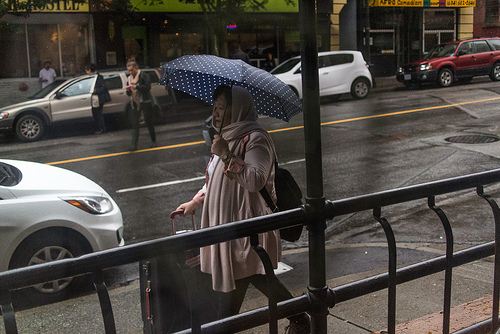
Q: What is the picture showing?
A: It is showing a street.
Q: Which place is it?
A: It is a street.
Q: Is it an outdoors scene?
A: Yes, it is outdoors.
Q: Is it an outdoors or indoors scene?
A: It is outdoors.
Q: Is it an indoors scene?
A: No, it is outdoors.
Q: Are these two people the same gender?
A: Yes, all the people are female.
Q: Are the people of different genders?
A: No, all the people are female.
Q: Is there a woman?
A: Yes, there is a woman.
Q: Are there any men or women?
A: Yes, there is a woman.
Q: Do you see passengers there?
A: No, there are no passengers.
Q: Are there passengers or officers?
A: No, there are no passengers or officers.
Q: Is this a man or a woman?
A: This is a woman.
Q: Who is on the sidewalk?
A: The woman is on the sidewalk.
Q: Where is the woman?
A: The woman is on the sidewalk.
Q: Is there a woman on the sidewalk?
A: Yes, there is a woman on the sidewalk.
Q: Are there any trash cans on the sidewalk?
A: No, there is a woman on the sidewalk.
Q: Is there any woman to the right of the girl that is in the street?
A: Yes, there is a woman to the right of the girl.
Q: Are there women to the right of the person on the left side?
A: Yes, there is a woman to the right of the girl.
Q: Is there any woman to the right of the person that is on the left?
A: Yes, there is a woman to the right of the girl.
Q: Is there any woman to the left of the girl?
A: No, the woman is to the right of the girl.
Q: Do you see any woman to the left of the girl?
A: No, the woman is to the right of the girl.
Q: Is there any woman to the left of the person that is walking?
A: No, the woman is to the right of the girl.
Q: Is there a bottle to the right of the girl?
A: No, there is a woman to the right of the girl.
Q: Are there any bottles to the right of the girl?
A: No, there is a woman to the right of the girl.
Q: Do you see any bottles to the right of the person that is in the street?
A: No, there is a woman to the right of the girl.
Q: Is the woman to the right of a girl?
A: Yes, the woman is to the right of a girl.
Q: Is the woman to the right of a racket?
A: No, the woman is to the right of a girl.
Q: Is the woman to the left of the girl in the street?
A: No, the woman is to the right of the girl.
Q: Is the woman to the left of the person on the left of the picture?
A: No, the woman is to the right of the girl.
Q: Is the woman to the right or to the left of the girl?
A: The woman is to the right of the girl.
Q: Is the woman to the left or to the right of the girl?
A: The woman is to the right of the girl.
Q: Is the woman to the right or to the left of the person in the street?
A: The woman is to the right of the girl.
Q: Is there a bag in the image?
A: Yes, there is a bag.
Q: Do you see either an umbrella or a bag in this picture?
A: Yes, there is a bag.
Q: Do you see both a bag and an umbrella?
A: Yes, there are both a bag and an umbrella.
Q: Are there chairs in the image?
A: No, there are no chairs.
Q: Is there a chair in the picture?
A: No, there are no chairs.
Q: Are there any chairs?
A: No, there are no chairs.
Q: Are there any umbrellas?
A: Yes, there is an umbrella.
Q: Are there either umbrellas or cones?
A: Yes, there is an umbrella.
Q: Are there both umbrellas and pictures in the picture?
A: No, there is an umbrella but no pictures.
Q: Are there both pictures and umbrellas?
A: No, there is an umbrella but no pictures.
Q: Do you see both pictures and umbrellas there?
A: No, there is an umbrella but no pictures.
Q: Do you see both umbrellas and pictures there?
A: No, there is an umbrella but no pictures.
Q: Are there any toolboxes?
A: No, there are no toolboxes.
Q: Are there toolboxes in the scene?
A: No, there are no toolboxes.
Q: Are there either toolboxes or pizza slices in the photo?
A: No, there are no toolboxes or pizza slices.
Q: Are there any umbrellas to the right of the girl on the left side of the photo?
A: Yes, there is an umbrella to the right of the girl.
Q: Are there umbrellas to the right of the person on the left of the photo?
A: Yes, there is an umbrella to the right of the girl.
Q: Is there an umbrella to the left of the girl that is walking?
A: No, the umbrella is to the right of the girl.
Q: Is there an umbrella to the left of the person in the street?
A: No, the umbrella is to the right of the girl.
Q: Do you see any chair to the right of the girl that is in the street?
A: No, there is an umbrella to the right of the girl.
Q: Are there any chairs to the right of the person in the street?
A: No, there is an umbrella to the right of the girl.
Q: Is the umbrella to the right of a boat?
A: No, the umbrella is to the right of the girl.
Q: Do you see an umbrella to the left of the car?
A: Yes, there is an umbrella to the left of the car.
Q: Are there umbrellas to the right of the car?
A: No, the umbrella is to the left of the car.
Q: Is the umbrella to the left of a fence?
A: No, the umbrella is to the left of a car.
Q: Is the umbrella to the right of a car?
A: No, the umbrella is to the left of a car.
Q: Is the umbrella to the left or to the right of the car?
A: The umbrella is to the left of the car.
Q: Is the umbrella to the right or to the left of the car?
A: The umbrella is to the left of the car.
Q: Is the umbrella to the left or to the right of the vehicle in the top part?
A: The umbrella is to the left of the car.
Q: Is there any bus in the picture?
A: No, there are no buses.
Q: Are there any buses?
A: No, there are no buses.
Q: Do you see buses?
A: No, there are no buses.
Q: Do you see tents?
A: No, there are no tents.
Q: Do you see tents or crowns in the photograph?
A: No, there are no tents or crowns.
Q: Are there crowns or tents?
A: No, there are no tents or crowns.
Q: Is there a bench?
A: No, there are no benches.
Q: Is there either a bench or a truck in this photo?
A: No, there are no benches or trucks.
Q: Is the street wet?
A: Yes, the street is wet.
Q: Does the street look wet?
A: Yes, the street is wet.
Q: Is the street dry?
A: No, the street is wet.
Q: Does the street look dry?
A: No, the street is wet.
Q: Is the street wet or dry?
A: The street is wet.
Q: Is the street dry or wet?
A: The street is wet.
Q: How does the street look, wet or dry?
A: The street is wet.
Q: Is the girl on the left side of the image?
A: Yes, the girl is on the left of the image.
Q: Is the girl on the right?
A: No, the girl is on the left of the image.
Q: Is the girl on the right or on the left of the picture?
A: The girl is on the left of the image.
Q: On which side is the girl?
A: The girl is on the left of the image.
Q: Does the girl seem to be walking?
A: Yes, the girl is walking.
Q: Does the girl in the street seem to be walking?
A: Yes, the girl is walking.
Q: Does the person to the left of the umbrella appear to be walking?
A: Yes, the girl is walking.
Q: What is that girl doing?
A: The girl is walking.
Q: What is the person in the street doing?
A: The girl is walking.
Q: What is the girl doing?
A: The girl is walking.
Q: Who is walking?
A: The girl is walking.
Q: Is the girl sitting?
A: No, the girl is walking.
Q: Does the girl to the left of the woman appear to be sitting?
A: No, the girl is walking.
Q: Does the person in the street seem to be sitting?
A: No, the girl is walking.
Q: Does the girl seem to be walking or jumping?
A: The girl is walking.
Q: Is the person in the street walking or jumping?
A: The girl is walking.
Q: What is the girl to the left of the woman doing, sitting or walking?
A: The girl is walking.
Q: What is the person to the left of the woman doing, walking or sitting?
A: The girl is walking.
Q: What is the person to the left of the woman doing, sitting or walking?
A: The girl is walking.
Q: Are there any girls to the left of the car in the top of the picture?
A: Yes, there is a girl to the left of the car.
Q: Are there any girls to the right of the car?
A: No, the girl is to the left of the car.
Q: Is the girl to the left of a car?
A: Yes, the girl is to the left of a car.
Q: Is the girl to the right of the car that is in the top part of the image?
A: No, the girl is to the left of the car.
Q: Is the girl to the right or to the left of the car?
A: The girl is to the left of the car.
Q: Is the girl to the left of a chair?
A: No, the girl is to the left of the umbrella.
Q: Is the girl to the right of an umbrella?
A: No, the girl is to the left of an umbrella.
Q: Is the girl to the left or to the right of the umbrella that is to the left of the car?
A: The girl is to the left of the umbrella.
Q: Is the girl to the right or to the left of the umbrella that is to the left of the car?
A: The girl is to the left of the umbrella.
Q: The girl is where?
A: The girl is in the street.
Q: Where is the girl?
A: The girl is in the street.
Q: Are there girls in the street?
A: Yes, there is a girl in the street.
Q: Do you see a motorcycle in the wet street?
A: No, there is a girl in the street.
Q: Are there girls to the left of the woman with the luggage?
A: Yes, there is a girl to the left of the woman.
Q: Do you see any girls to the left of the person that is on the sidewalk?
A: Yes, there is a girl to the left of the woman.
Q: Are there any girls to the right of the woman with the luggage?
A: No, the girl is to the left of the woman.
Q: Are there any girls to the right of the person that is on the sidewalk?
A: No, the girl is to the left of the woman.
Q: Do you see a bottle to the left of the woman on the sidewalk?
A: No, there is a girl to the left of the woman.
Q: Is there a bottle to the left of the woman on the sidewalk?
A: No, there is a girl to the left of the woman.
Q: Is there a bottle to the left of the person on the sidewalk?
A: No, there is a girl to the left of the woman.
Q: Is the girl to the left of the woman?
A: Yes, the girl is to the left of the woman.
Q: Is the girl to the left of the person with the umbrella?
A: Yes, the girl is to the left of the woman.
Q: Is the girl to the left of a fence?
A: No, the girl is to the left of the woman.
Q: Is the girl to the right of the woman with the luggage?
A: No, the girl is to the left of the woman.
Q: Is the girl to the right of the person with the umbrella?
A: No, the girl is to the left of the woman.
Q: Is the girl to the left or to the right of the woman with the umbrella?
A: The girl is to the left of the woman.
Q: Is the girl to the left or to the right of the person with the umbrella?
A: The girl is to the left of the woman.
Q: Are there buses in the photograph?
A: No, there are no buses.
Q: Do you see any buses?
A: No, there are no buses.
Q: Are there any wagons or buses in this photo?
A: No, there are no buses or wagons.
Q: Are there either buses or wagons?
A: No, there are no buses or wagons.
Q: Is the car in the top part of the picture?
A: Yes, the car is in the top of the image.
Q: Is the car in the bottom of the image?
A: No, the car is in the top of the image.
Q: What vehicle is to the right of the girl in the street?
A: The vehicle is a car.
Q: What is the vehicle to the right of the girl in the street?
A: The vehicle is a car.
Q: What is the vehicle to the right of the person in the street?
A: The vehicle is a car.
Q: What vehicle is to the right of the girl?
A: The vehicle is a car.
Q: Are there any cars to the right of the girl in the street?
A: Yes, there is a car to the right of the girl.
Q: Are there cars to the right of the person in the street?
A: Yes, there is a car to the right of the girl.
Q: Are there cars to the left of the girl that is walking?
A: No, the car is to the right of the girl.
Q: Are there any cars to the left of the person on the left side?
A: No, the car is to the right of the girl.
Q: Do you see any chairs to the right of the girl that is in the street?
A: No, there is a car to the right of the girl.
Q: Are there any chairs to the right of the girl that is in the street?
A: No, there is a car to the right of the girl.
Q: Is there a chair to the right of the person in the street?
A: No, there is a car to the right of the girl.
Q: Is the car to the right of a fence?
A: No, the car is to the right of a girl.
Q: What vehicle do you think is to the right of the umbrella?
A: The vehicle is a car.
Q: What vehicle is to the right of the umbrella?
A: The vehicle is a car.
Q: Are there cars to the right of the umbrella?
A: Yes, there is a car to the right of the umbrella.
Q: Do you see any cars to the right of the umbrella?
A: Yes, there is a car to the right of the umbrella.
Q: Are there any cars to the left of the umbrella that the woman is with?
A: No, the car is to the right of the umbrella.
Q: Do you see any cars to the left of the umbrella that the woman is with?
A: No, the car is to the right of the umbrella.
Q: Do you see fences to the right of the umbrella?
A: No, there is a car to the right of the umbrella.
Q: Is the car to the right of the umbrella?
A: Yes, the car is to the right of the umbrella.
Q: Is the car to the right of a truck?
A: No, the car is to the right of the umbrella.